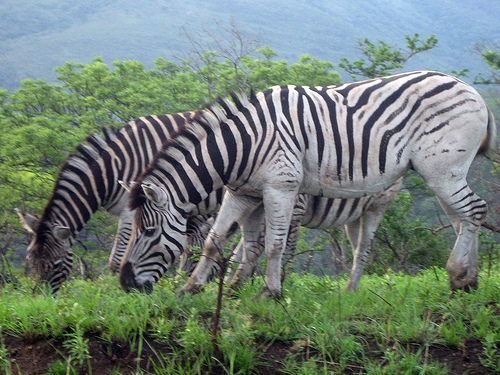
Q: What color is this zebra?
A: Black and white.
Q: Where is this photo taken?
A: In the wild.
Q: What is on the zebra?
A: Stripes.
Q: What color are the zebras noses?
A: Black.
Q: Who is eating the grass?
A: The zebra.